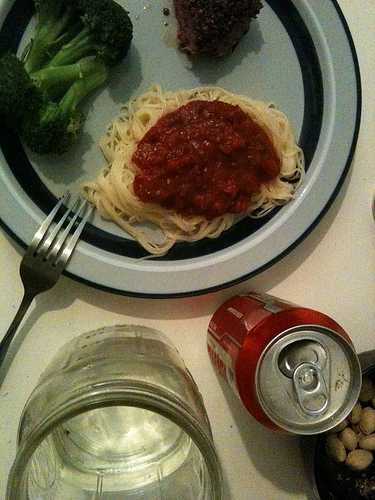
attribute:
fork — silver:
[4, 188, 111, 295]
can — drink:
[232, 276, 363, 431]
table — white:
[2, 2, 358, 498]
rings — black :
[25, 161, 258, 263]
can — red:
[205, 287, 363, 434]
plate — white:
[2, 0, 365, 300]